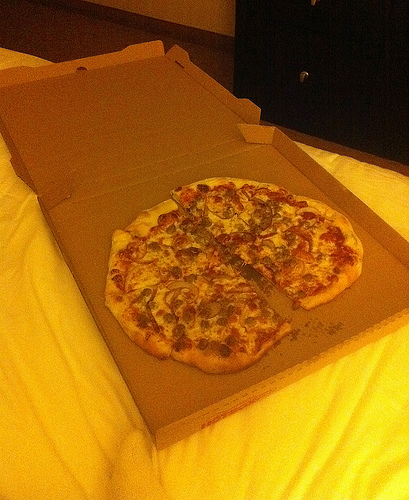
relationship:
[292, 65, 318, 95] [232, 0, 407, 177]
knob on front of furniture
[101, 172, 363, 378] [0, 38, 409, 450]
pizza inside cardboard box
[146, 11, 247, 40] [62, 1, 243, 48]
base trim on bottom of wall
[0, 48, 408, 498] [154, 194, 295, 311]
sheet under pizza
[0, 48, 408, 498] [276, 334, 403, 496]
sheet has creases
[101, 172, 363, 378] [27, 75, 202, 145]
pizza inside box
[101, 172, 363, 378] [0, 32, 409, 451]
pizza inside box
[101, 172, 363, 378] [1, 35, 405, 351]
pizza inside box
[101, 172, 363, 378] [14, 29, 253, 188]
pizza inside box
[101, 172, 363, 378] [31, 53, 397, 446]
pizza inside box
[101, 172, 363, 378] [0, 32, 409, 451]
pizza in box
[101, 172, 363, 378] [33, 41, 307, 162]
pizza in box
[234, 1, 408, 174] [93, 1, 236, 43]
dresser against wall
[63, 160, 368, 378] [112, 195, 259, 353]
cheese on pizza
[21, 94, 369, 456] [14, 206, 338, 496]
pizza box on bed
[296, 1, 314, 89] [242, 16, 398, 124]
knobs on dresser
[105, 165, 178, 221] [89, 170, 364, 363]
crust of pizza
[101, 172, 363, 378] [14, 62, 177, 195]
pizza in box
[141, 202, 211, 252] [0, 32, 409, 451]
pizza in box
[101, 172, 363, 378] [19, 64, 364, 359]
pizza in box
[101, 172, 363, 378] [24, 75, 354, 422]
pizza in box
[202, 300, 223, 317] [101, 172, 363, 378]
mushroom on pizza